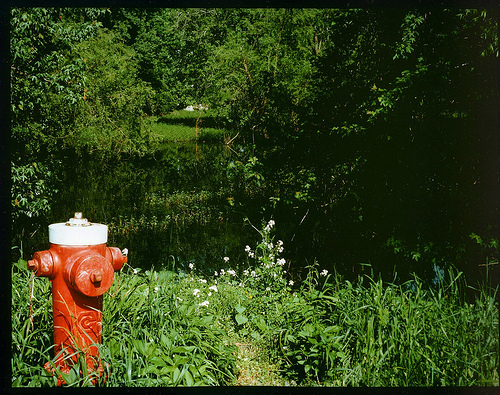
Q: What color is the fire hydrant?
A: Red and white.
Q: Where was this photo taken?
A: By a pond.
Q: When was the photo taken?
A: During the day.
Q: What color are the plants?
A: They are Green.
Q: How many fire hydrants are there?
A: Just 1.